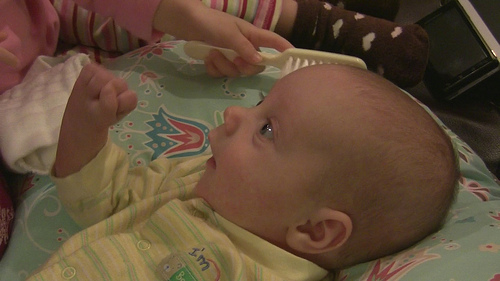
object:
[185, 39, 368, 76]
brush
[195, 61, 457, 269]
head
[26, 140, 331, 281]
pajamas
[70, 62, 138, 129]
hand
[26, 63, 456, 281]
baby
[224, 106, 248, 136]
nose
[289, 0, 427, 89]
sock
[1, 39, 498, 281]
pillow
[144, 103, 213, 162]
flower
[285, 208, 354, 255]
ear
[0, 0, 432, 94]
kid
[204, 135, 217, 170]
mouth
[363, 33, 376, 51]
heart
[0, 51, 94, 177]
towel